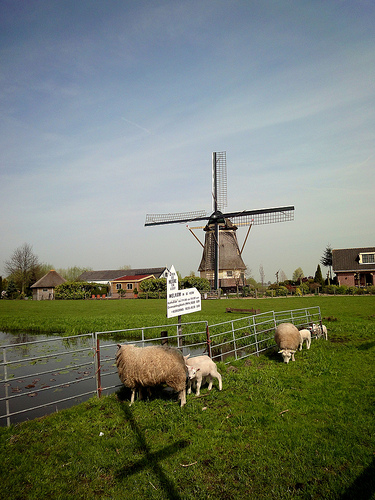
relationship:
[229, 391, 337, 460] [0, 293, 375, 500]
field of grass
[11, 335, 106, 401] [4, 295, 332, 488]
pond beside a field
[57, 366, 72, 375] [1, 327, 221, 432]
lily pad on a pond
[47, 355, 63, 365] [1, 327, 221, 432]
lily pad on a pond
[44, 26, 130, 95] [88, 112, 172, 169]
sky covered with clouds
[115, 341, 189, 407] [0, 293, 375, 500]
ram eating grass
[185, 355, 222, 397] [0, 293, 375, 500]
kid eating grass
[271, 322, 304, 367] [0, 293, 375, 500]
sheep eating grass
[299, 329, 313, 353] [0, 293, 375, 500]
sheep eating grass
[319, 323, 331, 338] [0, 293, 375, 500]
sheep eating grass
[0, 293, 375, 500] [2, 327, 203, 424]
grass near pond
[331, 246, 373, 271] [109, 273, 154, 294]
roof of building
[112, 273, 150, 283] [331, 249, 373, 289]
roof of building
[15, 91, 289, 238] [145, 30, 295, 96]
clouds in sky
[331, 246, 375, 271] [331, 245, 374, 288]
roof of building